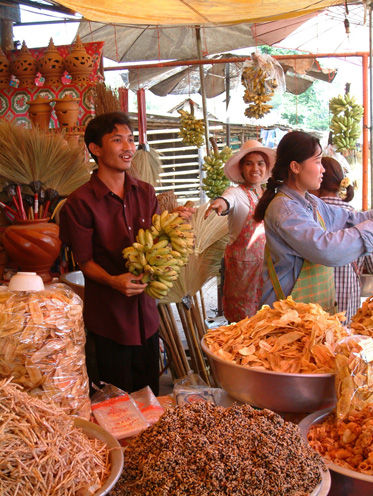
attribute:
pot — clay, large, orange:
[2, 222, 65, 287]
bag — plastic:
[92, 384, 167, 441]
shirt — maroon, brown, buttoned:
[57, 167, 165, 350]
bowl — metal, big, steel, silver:
[199, 326, 338, 424]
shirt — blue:
[259, 186, 371, 312]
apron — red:
[219, 186, 268, 323]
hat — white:
[223, 139, 275, 183]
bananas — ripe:
[122, 207, 200, 300]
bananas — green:
[242, 55, 282, 125]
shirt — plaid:
[317, 192, 363, 325]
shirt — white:
[212, 182, 269, 250]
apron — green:
[262, 193, 338, 317]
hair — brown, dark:
[83, 111, 133, 158]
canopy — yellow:
[49, 0, 357, 30]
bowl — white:
[5, 267, 53, 298]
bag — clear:
[234, 52, 291, 128]